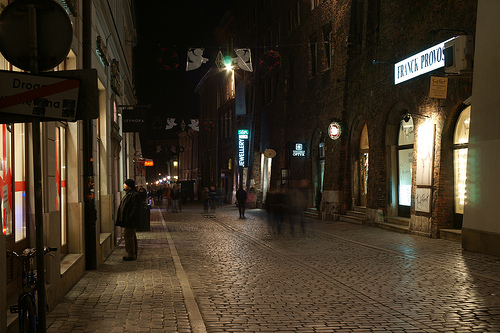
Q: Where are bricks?
A: On the ground.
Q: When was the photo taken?
A: Night.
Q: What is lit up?
A: A white sign.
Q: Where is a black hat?
A: On man's head.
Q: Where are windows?
A: On the buildings.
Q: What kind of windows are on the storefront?
A: Arched.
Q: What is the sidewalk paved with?
A: Bricks.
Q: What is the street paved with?
A: Cobblestones.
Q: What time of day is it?
A: It is night.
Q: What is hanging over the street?
A: Angel cutouts.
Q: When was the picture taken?
A: At night.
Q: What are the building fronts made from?
A: They are stone.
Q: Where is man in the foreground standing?
A: In front of a shop window.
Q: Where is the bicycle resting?
A: Against the sign post in the left of the photo.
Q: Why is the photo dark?
A: It is night time.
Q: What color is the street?
A: Gray.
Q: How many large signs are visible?
A: One.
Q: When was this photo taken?
A: Night time.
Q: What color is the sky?
A: Black.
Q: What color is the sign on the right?
A: White.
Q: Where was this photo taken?
A: On the sidewalk.